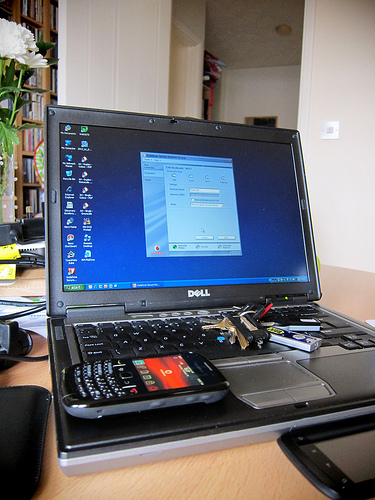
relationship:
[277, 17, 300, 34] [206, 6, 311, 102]
detector on ceiling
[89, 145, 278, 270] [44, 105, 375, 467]
screen on computer